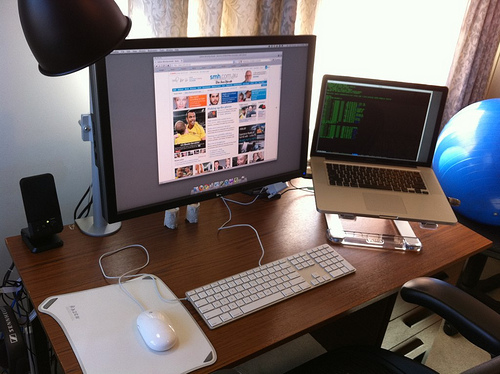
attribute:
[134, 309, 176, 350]
mouse — white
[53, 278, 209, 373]
mouse pad — white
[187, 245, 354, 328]
keyboard — white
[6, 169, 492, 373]
desk — wooden, dark wood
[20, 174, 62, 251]
speaker — black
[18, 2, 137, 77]
lamp — black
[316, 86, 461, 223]
laptop — open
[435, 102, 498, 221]
ball — blue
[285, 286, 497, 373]
chair — dark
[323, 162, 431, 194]
keyboard — black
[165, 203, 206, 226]
support — clear plastic